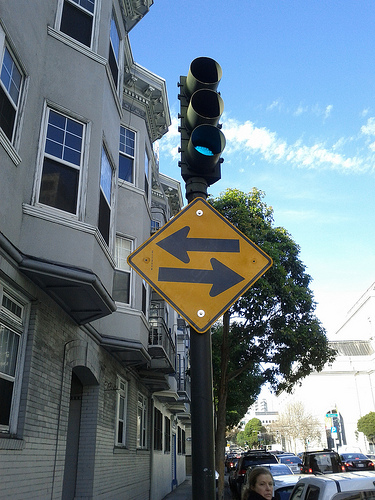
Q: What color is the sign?
A: Yellow.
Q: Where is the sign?
A: On the pole.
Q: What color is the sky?
A: Blue.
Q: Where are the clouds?
A: In the sky.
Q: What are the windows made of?
A: Glass.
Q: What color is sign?
A: Yellow.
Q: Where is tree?
A: Behind sign.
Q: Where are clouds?
A: Sky.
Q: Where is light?
A: Above street.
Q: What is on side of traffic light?
A: Sign.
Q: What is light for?
A: Traffic.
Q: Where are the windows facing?
A: The road.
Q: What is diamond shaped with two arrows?
A: The sign.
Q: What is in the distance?
A: A large white building.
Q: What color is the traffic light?
A: Green.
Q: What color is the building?
A: Gray.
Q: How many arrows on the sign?
A: Two.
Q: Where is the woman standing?
A: On the street.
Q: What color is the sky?
A: Blue.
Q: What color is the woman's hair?
A: Brown.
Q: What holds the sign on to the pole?
A: Bolts.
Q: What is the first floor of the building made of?
A: Bricks.